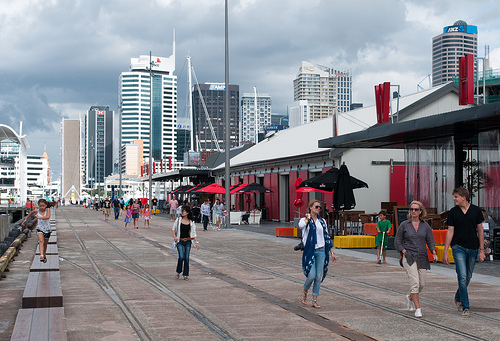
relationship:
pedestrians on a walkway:
[99, 196, 150, 226] [220, 236, 283, 320]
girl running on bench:
[27, 200, 53, 263] [22, 271, 64, 305]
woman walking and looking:
[172, 207, 199, 278] [179, 207, 190, 221]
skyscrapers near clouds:
[120, 52, 238, 151] [86, 6, 163, 44]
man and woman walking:
[445, 188, 490, 316] [394, 186, 487, 319]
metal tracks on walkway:
[101, 257, 130, 308] [220, 236, 283, 320]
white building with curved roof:
[285, 130, 309, 153] [273, 127, 307, 155]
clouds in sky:
[86, 6, 163, 44] [92, 1, 212, 26]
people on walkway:
[80, 198, 98, 211] [220, 236, 283, 320]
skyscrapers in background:
[120, 52, 238, 151] [63, 33, 352, 106]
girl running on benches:
[27, 200, 53, 263] [21, 262, 63, 340]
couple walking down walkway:
[201, 198, 230, 230] [220, 236, 283, 320]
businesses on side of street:
[118, 144, 398, 202] [388, 325, 425, 338]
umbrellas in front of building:
[175, 182, 223, 197] [211, 82, 479, 224]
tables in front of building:
[233, 207, 262, 226] [211, 82, 479, 224]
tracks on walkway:
[66, 231, 118, 256] [220, 236, 283, 320]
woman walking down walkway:
[172, 207, 199, 278] [220, 236, 283, 320]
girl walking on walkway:
[294, 198, 338, 305] [220, 236, 283, 320]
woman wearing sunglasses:
[172, 207, 199, 278] [180, 209, 186, 214]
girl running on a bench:
[27, 200, 53, 263] [22, 271, 64, 305]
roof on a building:
[273, 127, 307, 155] [227, 114, 374, 220]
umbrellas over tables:
[175, 182, 223, 197] [233, 207, 262, 226]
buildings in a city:
[59, 34, 192, 195] [2, 8, 499, 299]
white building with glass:
[166, 62, 173, 74] [125, 78, 169, 127]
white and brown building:
[166, 62, 173, 74] [58, 115, 84, 202]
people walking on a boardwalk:
[80, 198, 98, 211] [68, 215, 126, 268]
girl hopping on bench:
[27, 200, 53, 263] [22, 271, 64, 305]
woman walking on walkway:
[172, 207, 199, 278] [220, 236, 283, 320]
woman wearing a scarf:
[294, 198, 338, 305] [307, 223, 314, 261]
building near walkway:
[211, 82, 479, 224] [220, 236, 283, 320]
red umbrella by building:
[210, 184, 220, 193] [211, 82, 479, 224]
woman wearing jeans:
[172, 207, 199, 278] [177, 242, 191, 275]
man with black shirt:
[445, 188, 490, 316] [448, 207, 484, 248]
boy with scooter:
[373, 209, 391, 266] [377, 229, 388, 266]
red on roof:
[457, 54, 474, 110] [273, 127, 307, 155]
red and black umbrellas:
[210, 184, 220, 193] [175, 182, 223, 197]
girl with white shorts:
[143, 205, 151, 228] [144, 215, 151, 221]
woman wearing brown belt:
[172, 207, 199, 278] [178, 237, 195, 242]